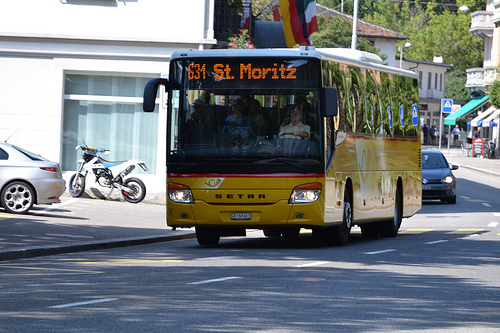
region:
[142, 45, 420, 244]
yellow bus on road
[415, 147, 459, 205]
car behind yellow bus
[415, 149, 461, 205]
car on paved road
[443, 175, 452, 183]
car headlight is on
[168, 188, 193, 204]
bus headlight is on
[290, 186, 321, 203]
bus headlight is on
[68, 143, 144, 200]
motorcycle parked on sidewalk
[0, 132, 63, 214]
silver car on road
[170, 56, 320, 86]
marquee on yellow bus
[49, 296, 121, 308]
white line on road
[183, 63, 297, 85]
destination sign on the bus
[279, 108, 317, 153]
bus driver steering the bus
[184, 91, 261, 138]
several passengers on the bus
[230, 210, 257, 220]
license plate on front of bus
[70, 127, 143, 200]
a motorcycle parked near window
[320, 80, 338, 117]
a side view mirror on the bus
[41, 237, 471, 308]
white pavement markings on street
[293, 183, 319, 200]
a large headlight on front of bus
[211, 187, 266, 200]
the name of the bus company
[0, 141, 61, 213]
back of gray car parked in lot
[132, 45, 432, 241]
a yellow city bus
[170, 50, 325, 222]
the front of a bus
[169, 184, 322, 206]
the headlights of a bus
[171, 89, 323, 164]
the windshield of a bus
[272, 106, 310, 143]
the driver of a bus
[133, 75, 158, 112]
the mirror of a bus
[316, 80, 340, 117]
the mirror of a bus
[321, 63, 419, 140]
the windows of a bus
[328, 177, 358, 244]
the front wheel of a bus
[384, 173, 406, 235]
the rear wheel of a bus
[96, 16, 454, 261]
the bus is yellow, black, and red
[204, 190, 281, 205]
the logo says "SETRA"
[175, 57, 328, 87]
the screen reads 631 St. Moritz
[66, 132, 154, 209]
the motorcycle is parked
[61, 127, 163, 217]
the motorbike is parked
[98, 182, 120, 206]
a silver kick stand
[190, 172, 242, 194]
there is a decal of a french horn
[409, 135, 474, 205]
grey volkswagen car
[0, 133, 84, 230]
a silver car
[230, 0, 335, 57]
there are a lot of flags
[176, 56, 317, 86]
Sign on front of yellow bus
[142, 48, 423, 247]
Yellow bus driving down the road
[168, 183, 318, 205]
Headlights on front of yellow bus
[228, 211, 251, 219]
License plate on front of bus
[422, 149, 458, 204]
Car driving behind bus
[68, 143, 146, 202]
Motorcycle parked next to building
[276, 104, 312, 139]
Man in yellow shirt driving bus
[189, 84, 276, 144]
Passengers sitting inside of bus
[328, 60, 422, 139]
Group of windows on side of bus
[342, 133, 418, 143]
Red stripe on side of yellow bus